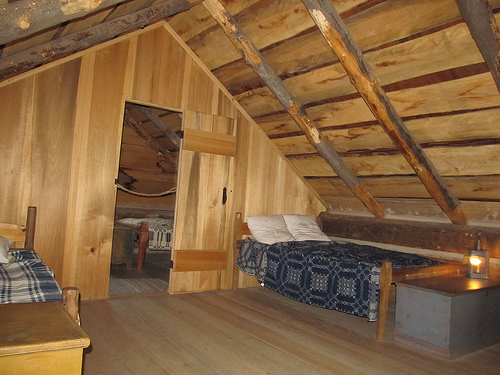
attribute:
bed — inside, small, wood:
[235, 214, 465, 345]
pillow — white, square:
[246, 214, 291, 245]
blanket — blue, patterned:
[268, 241, 444, 319]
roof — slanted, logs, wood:
[1, 1, 500, 233]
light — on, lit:
[465, 237, 488, 279]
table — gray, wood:
[396, 267, 500, 359]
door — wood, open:
[169, 112, 239, 294]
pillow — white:
[1, 235, 13, 262]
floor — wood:
[76, 257, 500, 374]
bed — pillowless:
[113, 216, 174, 271]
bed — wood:
[1, 208, 80, 321]